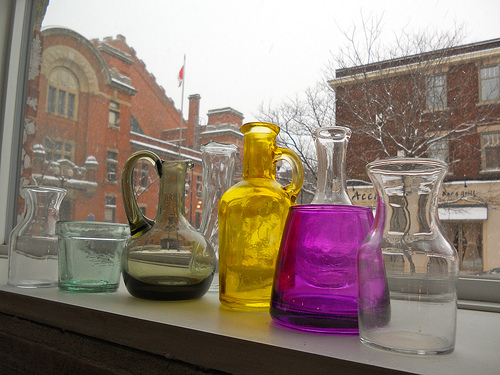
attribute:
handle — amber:
[267, 133, 308, 201]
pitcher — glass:
[215, 110, 292, 285]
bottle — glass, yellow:
[218, 109, 302, 324]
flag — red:
[172, 49, 189, 114]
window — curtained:
[414, 66, 465, 116]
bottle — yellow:
[208, 107, 310, 316]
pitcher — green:
[119, 133, 216, 300]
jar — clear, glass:
[55, 222, 128, 292]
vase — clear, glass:
[301, 203, 381, 294]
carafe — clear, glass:
[9, 180, 70, 292]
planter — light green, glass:
[70, 223, 115, 293]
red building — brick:
[30, 27, 240, 240]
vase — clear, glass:
[355, 156, 461, 355]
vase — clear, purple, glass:
[278, 204, 389, 317]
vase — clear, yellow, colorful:
[218, 119, 287, 309]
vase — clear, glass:
[9, 182, 67, 286]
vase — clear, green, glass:
[117, 149, 216, 299]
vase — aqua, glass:
[58, 217, 129, 293]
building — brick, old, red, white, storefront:
[39, 24, 243, 229]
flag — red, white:
[177, 66, 187, 86]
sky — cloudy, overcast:
[95, 4, 400, 101]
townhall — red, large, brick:
[14, 24, 241, 230]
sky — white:
[36, 0, 498, 179]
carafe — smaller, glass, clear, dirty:
[6, 180, 67, 286]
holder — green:
[55, 218, 135, 294]